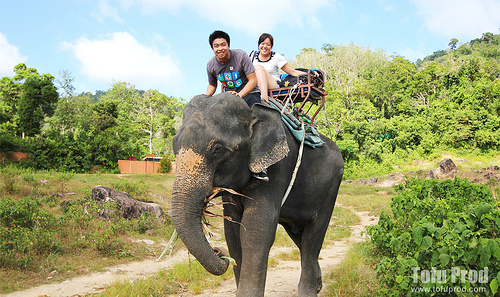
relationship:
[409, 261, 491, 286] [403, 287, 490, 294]
name in lettering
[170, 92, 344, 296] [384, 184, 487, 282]
elephant eating foliage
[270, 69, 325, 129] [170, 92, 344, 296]
red seating on elephant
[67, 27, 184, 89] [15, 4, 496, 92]
cloud in sky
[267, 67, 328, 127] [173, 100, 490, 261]
red seating on top of elephant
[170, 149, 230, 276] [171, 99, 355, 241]
grass trunk of an elephant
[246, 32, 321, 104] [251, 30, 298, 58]
person with a face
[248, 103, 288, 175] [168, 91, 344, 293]
ear of an elephant